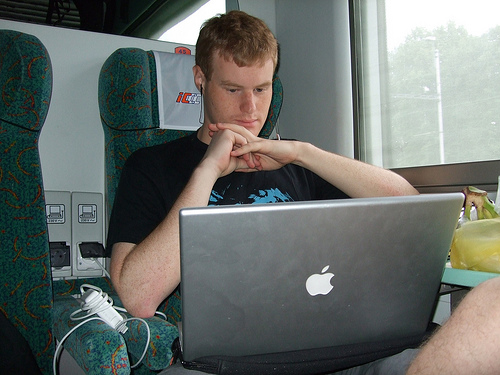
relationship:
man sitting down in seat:
[100, 9, 499, 372] [93, 42, 475, 372]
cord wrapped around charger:
[50, 282, 166, 372] [77, 287, 130, 336]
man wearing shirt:
[100, 9, 499, 372] [102, 126, 351, 256]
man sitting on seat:
[100, 9, 499, 372] [93, 42, 475, 372]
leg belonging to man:
[400, 273, 485, 373] [100, 9, 499, 372]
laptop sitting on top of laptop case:
[176, 190, 466, 361] [170, 319, 443, 373]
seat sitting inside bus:
[1, 28, 134, 373] [3, 2, 484, 370]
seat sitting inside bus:
[93, 40, 285, 371] [3, 2, 484, 370]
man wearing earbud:
[100, 9, 499, 372] [198, 76, 204, 95]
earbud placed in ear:
[198, 76, 204, 95] [190, 62, 207, 93]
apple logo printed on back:
[305, 265, 335, 297] [178, 190, 466, 362]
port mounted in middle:
[75, 240, 107, 274] [37, 25, 107, 281]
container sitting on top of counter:
[450, 212, 482, 274] [440, 255, 484, 288]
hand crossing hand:
[204, 119, 295, 173] [202, 123, 264, 174]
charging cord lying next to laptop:
[48, 280, 168, 372] [176, 190, 466, 361]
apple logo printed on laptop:
[302, 262, 335, 299] [179, 191, 466, 362]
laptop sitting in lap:
[176, 190, 466, 361] [151, 339, 427, 373]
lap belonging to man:
[151, 339, 427, 373] [100, 9, 499, 372]